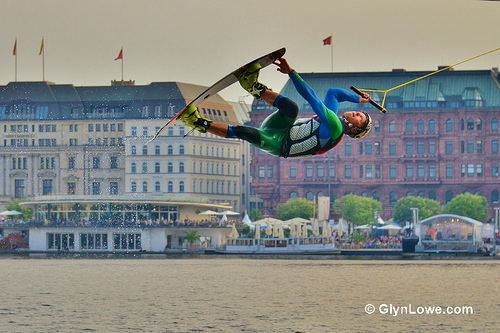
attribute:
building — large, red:
[245, 66, 499, 226]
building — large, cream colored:
[0, 78, 253, 224]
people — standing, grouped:
[333, 232, 409, 252]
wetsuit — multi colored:
[223, 69, 359, 157]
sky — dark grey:
[0, 0, 499, 106]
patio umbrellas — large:
[198, 209, 403, 245]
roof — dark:
[1, 80, 241, 125]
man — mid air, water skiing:
[181, 57, 372, 157]